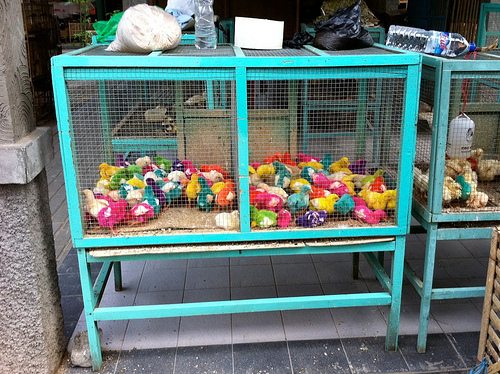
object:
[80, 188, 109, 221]
bird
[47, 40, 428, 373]
cage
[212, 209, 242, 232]
bird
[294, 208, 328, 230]
bird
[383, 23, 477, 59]
bottle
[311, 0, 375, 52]
bag